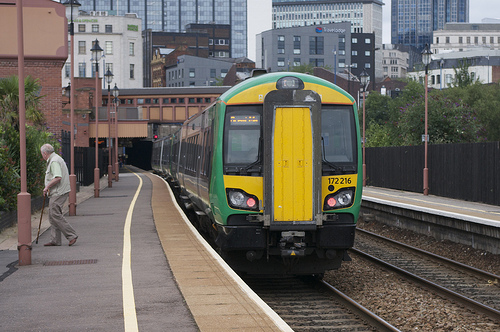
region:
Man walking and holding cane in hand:
[33, 143, 78, 246]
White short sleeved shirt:
[43, 150, 72, 195]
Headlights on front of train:
[226, 184, 356, 213]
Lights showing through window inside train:
[228, 112, 258, 123]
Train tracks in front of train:
[243, 281, 400, 329]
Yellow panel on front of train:
[273, 103, 313, 219]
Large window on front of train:
[320, 104, 357, 174]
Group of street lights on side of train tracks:
[59, 0, 119, 216]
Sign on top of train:
[274, 75, 304, 87]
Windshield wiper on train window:
[237, 137, 267, 175]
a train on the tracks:
[122, 68, 496, 292]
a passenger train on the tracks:
[149, 80, 458, 322]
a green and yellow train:
[117, 36, 375, 310]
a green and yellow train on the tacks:
[132, 75, 454, 137]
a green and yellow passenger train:
[129, 91, 398, 287]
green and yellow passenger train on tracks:
[137, 58, 434, 329]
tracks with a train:
[133, 40, 413, 314]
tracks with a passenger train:
[154, 26, 454, 316]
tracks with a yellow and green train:
[112, 37, 377, 322]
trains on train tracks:
[123, 41, 481, 331]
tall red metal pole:
[13, 1, 35, 264]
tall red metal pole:
[66, 22, 78, 214]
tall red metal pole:
[91, 70, 103, 199]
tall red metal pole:
[105, 91, 115, 184]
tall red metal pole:
[111, 102, 121, 182]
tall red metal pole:
[421, 71, 429, 197]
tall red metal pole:
[360, 90, 367, 187]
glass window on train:
[321, 105, 354, 171]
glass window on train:
[222, 107, 262, 172]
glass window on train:
[198, 127, 208, 171]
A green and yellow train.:
[182, 62, 377, 292]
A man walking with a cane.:
[32, 137, 85, 252]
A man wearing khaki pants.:
[32, 142, 88, 251]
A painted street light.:
[87, 35, 109, 200]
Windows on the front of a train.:
[220, 97, 360, 192]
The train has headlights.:
[207, 65, 372, 265]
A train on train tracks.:
[209, 68, 490, 327]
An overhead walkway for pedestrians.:
[73, 78, 229, 130]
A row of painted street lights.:
[10, 3, 128, 243]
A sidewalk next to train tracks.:
[92, 144, 279, 330]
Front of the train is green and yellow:
[211, 68, 364, 224]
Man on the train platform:
[2, 142, 296, 330]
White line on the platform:
[118, 162, 145, 330]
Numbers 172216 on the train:
[323, 170, 354, 188]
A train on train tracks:
[150, 67, 498, 329]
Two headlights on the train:
[222, 184, 358, 217]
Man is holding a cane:
[32, 138, 86, 252]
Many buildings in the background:
[62, 2, 498, 87]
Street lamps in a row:
[11, 0, 121, 269]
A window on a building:
[100, 37, 118, 60]